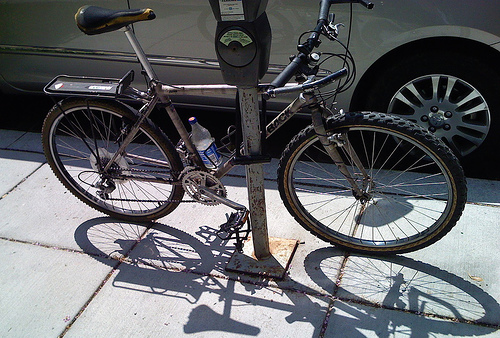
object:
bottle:
[185, 117, 221, 170]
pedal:
[219, 208, 249, 235]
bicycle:
[35, 0, 470, 259]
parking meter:
[205, 0, 278, 88]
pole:
[235, 77, 274, 264]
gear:
[180, 168, 227, 208]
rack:
[41, 66, 137, 101]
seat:
[69, 1, 159, 38]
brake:
[299, 72, 317, 103]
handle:
[265, 1, 377, 92]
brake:
[322, 11, 349, 42]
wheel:
[357, 51, 498, 176]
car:
[1, 0, 500, 177]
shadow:
[0, 85, 500, 206]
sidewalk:
[1, 127, 498, 337]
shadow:
[70, 212, 499, 337]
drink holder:
[179, 134, 221, 170]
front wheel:
[270, 105, 472, 259]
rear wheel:
[33, 92, 189, 224]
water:
[195, 140, 223, 170]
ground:
[0, 125, 500, 338]